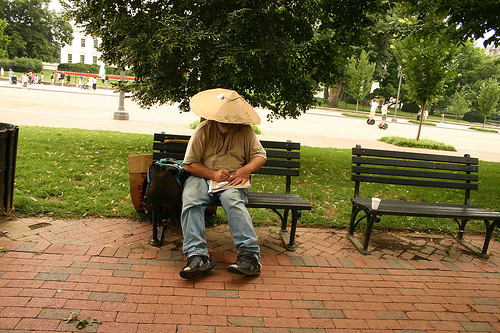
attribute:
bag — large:
[112, 143, 167, 210]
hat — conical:
[190, 88, 265, 125]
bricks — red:
[84, 286, 451, 331]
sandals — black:
[184, 249, 260, 279]